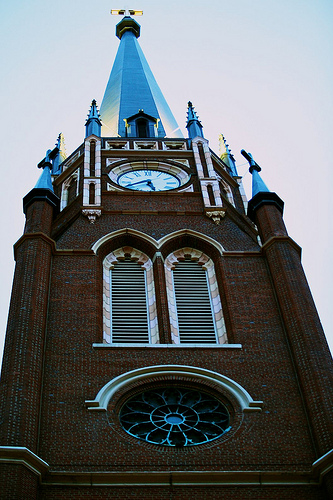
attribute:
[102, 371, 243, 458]
window — ornate, round, paned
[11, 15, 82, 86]
sky — blue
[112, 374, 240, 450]
window — circular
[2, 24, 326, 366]
picture — daytime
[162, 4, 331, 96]
sky — clear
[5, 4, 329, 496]
clocktower — brown, brick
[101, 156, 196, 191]
clock — white, black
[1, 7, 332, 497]
building — brick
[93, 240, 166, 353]
window — arched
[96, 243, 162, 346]
boarder — tiled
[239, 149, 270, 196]
cross — blue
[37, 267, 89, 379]
tower — brown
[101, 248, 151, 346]
window — arched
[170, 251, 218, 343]
window — arched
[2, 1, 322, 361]
sky — blue